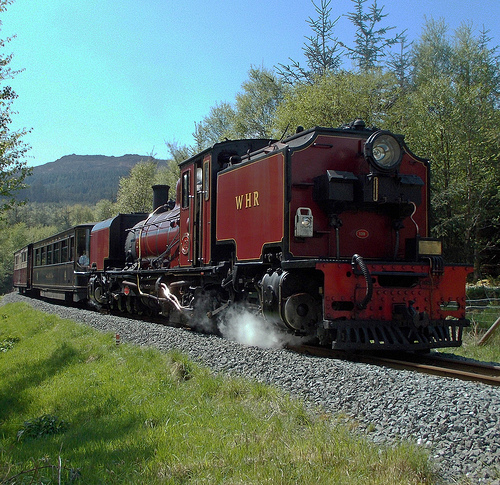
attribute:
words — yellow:
[231, 189, 265, 209]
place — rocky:
[347, 350, 480, 452]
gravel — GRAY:
[3, 287, 480, 479]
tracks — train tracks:
[365, 337, 498, 389]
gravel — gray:
[297, 355, 496, 448]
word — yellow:
[234, 188, 265, 210]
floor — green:
[15, 346, 417, 388]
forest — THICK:
[94, 0, 498, 285]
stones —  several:
[296, 362, 351, 389]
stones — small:
[435, 382, 465, 454]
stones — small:
[344, 375, 376, 417]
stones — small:
[253, 362, 323, 402]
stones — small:
[199, 338, 240, 368]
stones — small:
[92, 302, 157, 350]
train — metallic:
[70, 32, 498, 409]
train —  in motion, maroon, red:
[14, 116, 471, 351]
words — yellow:
[231, 187, 261, 209]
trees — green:
[421, 42, 481, 102]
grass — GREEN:
[35, 369, 245, 461]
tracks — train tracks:
[3, 282, 498, 401]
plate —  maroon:
[210, 147, 286, 259]